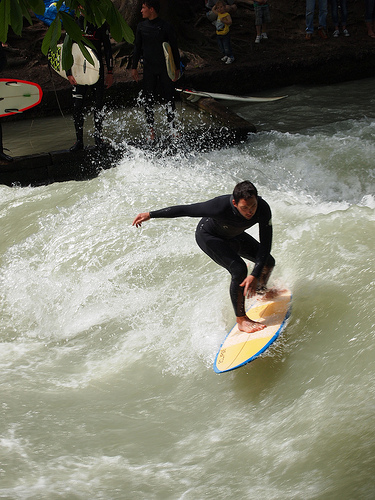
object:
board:
[210, 288, 295, 376]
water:
[0, 244, 132, 494]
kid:
[211, 0, 235, 65]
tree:
[0, 0, 139, 75]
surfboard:
[45, 40, 100, 88]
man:
[132, 178, 280, 333]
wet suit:
[149, 193, 275, 317]